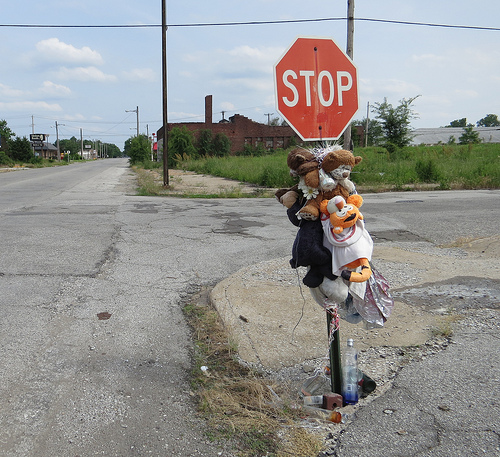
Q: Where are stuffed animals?
A: Attached to sign.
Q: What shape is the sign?
A: Octagon.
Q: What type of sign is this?
A: Stop sign.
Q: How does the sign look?
A: It's rusting.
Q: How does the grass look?
A: Dried out.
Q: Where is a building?
A: Building is in background.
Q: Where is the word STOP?
A: On the sign.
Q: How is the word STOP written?
A: In capital letters.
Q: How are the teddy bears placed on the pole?
A: There is a wire keeping them there.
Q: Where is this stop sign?
A: In a four way road.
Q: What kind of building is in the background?
A: A red building.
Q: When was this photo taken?
A: During the day time.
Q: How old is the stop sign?
A: Old enough to be stained and have holes in it.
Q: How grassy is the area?
A: It is very grassy.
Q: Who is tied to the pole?
A: A generic teddy bear.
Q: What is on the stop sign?
A: Stuffed Animals.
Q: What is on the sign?
A: Dolls.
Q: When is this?
A: Daytime.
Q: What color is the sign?
A: Red.